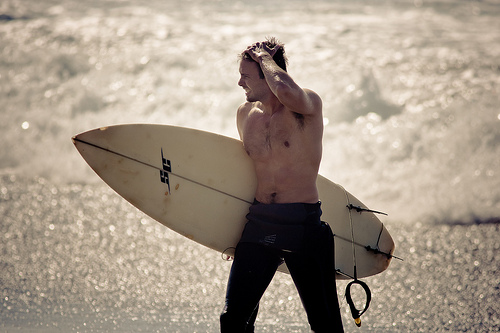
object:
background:
[7, 2, 498, 228]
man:
[218, 37, 346, 332]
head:
[237, 40, 287, 102]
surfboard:
[70, 123, 396, 281]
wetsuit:
[221, 199, 345, 332]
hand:
[241, 40, 281, 60]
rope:
[341, 185, 372, 326]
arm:
[259, 57, 320, 115]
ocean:
[1, 0, 500, 331]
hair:
[239, 36, 290, 74]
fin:
[347, 203, 388, 217]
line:
[73, 136, 394, 262]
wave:
[378, 210, 499, 229]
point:
[71, 127, 92, 154]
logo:
[159, 147, 171, 195]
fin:
[365, 246, 404, 262]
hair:
[291, 109, 306, 132]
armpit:
[292, 112, 308, 128]